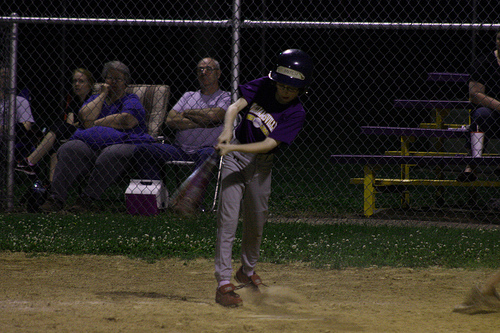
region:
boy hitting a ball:
[210, 35, 338, 301]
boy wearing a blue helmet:
[205, 20, 316, 307]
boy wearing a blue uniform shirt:
[200, 32, 320, 303]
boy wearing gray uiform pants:
[195, 32, 306, 307]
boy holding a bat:
[180, 26, 328, 314]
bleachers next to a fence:
[380, 25, 482, 267]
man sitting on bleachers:
[470, 35, 495, 126]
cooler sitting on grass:
[117, 165, 182, 218]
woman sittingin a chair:
[67, 60, 152, 171]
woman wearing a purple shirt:
[75, 55, 150, 165]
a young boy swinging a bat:
[144, 47, 316, 263]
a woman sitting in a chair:
[65, 62, 163, 188]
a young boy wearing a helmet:
[250, 56, 315, 114]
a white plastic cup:
[466, 117, 489, 165]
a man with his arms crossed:
[170, 51, 228, 146]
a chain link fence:
[17, 17, 433, 168]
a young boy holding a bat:
[198, 42, 320, 236]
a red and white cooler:
[113, 175, 174, 216]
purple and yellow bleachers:
[346, 97, 458, 212]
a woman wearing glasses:
[85, 65, 142, 134]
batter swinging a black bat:
[210, 42, 320, 307]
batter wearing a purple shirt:
[214, 47, 316, 307]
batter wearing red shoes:
[208, 45, 323, 305]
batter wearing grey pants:
[212, 45, 315, 302]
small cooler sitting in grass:
[126, 177, 167, 212]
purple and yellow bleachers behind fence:
[329, 60, 496, 216]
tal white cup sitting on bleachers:
[470, 129, 485, 159]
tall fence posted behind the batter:
[3, 0, 494, 220]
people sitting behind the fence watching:
[3, 35, 243, 217]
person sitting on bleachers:
[449, 21, 497, 186]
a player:
[125, 56, 257, 214]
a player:
[174, 66, 356, 328]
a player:
[116, 24, 428, 302]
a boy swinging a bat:
[176, 39, 338, 322]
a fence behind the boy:
[0, 4, 498, 262]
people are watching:
[3, 48, 257, 229]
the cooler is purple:
[98, 170, 174, 217]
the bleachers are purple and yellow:
[323, 47, 498, 234]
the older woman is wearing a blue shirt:
[41, 52, 157, 227]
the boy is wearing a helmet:
[250, 36, 331, 113]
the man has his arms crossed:
[145, 45, 254, 190]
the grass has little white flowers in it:
[9, 201, 499, 282]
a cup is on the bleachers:
[454, 109, 499, 173]